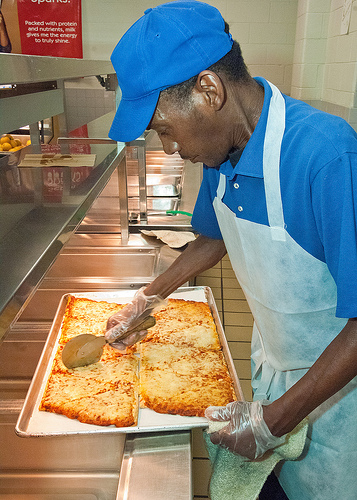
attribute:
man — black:
[106, 3, 356, 500]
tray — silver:
[13, 285, 248, 436]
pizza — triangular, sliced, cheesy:
[44, 296, 235, 432]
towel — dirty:
[209, 412, 310, 499]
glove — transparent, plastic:
[205, 403, 283, 463]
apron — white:
[211, 80, 357, 497]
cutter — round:
[62, 315, 158, 369]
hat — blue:
[105, 3, 232, 144]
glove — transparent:
[103, 290, 166, 351]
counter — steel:
[1, 144, 203, 498]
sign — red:
[17, 1, 80, 61]